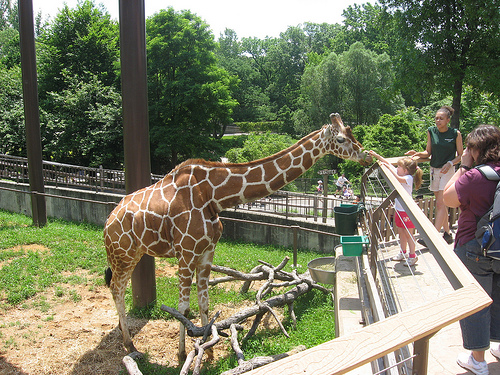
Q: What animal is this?
A: A giraffe.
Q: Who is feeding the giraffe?
A: The girl.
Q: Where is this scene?
A: A zoo.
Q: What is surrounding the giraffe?
A: A fence.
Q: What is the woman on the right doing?
A: Taking a photo.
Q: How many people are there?
A: Three.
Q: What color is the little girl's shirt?
A: White.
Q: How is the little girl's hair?
A: In a ponytail.